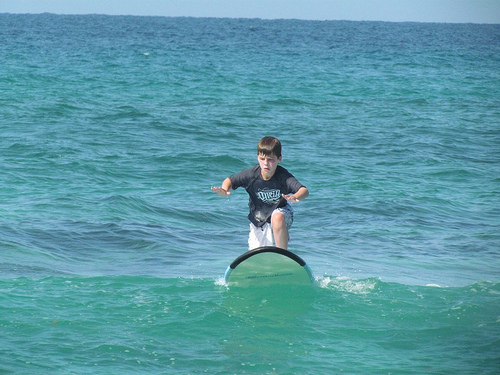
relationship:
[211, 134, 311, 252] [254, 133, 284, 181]
boy has head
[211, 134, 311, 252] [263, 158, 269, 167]
boy has nose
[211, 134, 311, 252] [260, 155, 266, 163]
boy has eye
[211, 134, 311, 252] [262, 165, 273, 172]
boy has mouth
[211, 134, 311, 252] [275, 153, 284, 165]
boy has ear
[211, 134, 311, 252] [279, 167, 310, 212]
boy has arm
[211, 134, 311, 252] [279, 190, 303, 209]
boy has hand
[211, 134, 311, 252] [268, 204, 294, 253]
boy has leg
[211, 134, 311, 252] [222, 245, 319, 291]
boy on top of surfboard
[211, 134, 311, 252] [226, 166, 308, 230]
boy wearing t-shirt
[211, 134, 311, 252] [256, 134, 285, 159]
boy has hair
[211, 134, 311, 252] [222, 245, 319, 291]
boy standing on surfboard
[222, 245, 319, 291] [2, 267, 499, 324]
surfboard sticking out of wave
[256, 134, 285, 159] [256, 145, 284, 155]
hair sticking to forehead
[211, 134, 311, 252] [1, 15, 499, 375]
boy surfing in water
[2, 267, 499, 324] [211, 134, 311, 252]
wave being used by boy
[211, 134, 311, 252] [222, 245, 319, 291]
boy balancing on surfboard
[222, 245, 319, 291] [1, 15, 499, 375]
surfboard coming out of water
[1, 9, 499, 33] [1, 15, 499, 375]
horizon at water